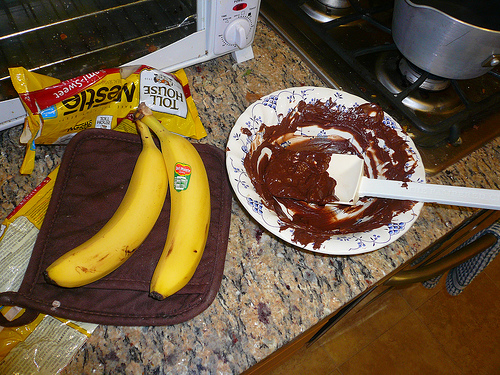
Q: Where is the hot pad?
A: Under the bananas.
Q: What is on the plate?
A: Chocolate.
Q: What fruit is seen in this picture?
A: Bananas.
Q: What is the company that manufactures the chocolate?
A: Nestle.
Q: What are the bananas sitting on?
A: An oven mitt.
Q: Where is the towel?
A: On the oven handlebar.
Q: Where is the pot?
A: On the stove.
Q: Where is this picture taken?
A: In the kitchen.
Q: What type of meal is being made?
A: Dessert.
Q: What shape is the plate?
A: Circle.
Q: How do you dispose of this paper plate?
A: In the trash.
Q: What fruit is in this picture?
A: Bananas.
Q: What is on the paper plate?
A: Chocolate.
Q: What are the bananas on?
A: A oven mitt.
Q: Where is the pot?
A: On the stove.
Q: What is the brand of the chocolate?
A: Nestle.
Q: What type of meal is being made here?
A: Dessert.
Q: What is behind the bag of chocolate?
A: A toaster oven.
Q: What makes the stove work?
A: Gas.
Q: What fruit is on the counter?
A: Bananas.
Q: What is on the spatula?
A: Chocolate.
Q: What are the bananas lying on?
A: A pot holder.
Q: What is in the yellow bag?
A: Chocolate chips.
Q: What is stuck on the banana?
A: A brand sticker.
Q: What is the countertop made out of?
A: Marble.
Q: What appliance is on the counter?
A: Toaster oven.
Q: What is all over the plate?
A: Chocolate.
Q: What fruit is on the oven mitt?
A: Bananas.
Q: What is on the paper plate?
A: Chocolate.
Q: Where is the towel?
A: On the handlebar of the oven.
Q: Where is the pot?
A: On the stove.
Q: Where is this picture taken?
A: In the kitchen.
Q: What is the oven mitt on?
A: An empty bag of chocolates.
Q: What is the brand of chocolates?
A: Nestle toll house chocolates.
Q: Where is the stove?
A: To the right.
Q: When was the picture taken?
A: During baking time.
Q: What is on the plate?
A: Melted chocolate.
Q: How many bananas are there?
A: Two.